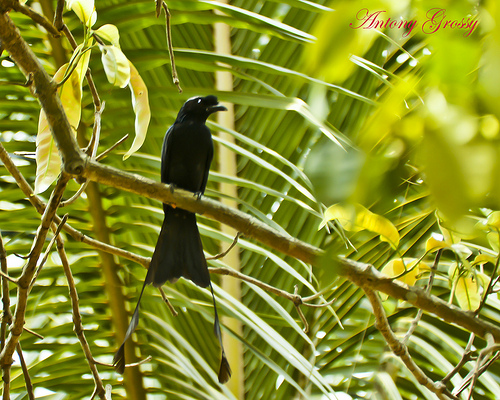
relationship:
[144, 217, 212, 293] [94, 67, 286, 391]
tail of bird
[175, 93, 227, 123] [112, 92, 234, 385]
head of bird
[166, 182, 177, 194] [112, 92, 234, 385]
foot of bird